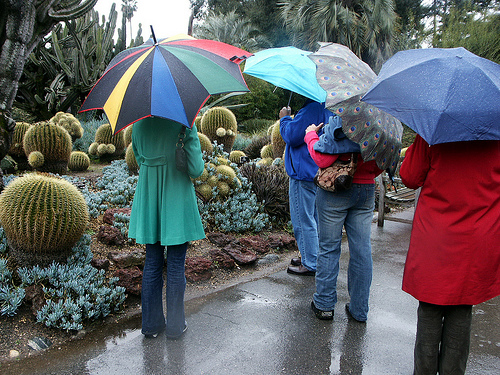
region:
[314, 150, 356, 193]
the bag on the woman's body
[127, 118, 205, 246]
the long green coat on the woman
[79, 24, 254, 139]
the multi colored umbrella with a decorative edge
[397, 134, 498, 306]
the long red coat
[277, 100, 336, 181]
the blue jacket on the man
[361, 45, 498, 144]
the dark blue umbrella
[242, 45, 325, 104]
the light blue umbrella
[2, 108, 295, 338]
the cactus on the ground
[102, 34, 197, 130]
the yellow on the umbrella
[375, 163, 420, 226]
the bench near the people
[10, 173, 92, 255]
cactus on the side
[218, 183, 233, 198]
cactus on the side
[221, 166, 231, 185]
cactus on the side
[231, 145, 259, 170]
cactus on the side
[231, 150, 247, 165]
cactus on the side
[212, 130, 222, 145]
cactus on the side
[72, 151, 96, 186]
cactus on the side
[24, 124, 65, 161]
cactus on the side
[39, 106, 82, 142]
cactus on the side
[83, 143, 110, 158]
cactus on the side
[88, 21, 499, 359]
people standing in the rain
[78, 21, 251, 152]
an umbrella in bright colors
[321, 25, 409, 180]
an umbrella that looks like a peacock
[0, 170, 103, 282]
big round cactus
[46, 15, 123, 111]
a very tall cactus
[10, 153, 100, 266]
a cactus with sharp needles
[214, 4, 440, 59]
trees among the cactus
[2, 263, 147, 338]
ground covering plants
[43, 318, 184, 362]
puddles from the rain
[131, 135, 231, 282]
a green rain coat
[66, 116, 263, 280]
a woman wearing a coat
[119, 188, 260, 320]
a woman wearing jeans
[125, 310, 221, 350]
a woman wearing shoes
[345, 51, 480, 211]
a woman holding a umbrella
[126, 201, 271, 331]
the long legs of a woman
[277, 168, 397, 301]
a woman wearing blue jeans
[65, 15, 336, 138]
a woman holding a colorful umbrella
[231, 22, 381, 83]
a woman holding a blue umbrella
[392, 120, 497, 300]
a woman wearing a red coat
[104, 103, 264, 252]
a woman wearing a green coat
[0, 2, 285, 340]
a garden planted with various cacti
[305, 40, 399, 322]
person with the peacock feather umbrella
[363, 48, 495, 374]
person with the blue umbrella and red coat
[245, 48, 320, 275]
person with the green umbrella and blue coat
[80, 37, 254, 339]
person with multicolored umbrella and green coat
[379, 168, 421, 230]
a wood park bench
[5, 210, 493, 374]
a wet sidewalk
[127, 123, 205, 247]
the green jacket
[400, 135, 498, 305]
a red jacket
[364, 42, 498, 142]
the blue umbrella on the right